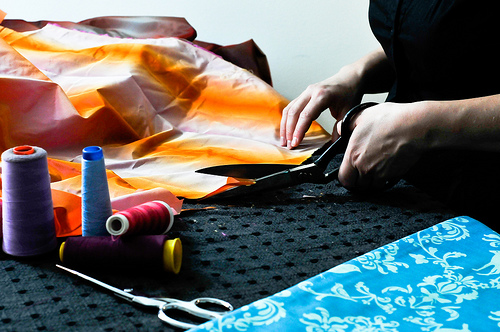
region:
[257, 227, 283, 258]
part of a cloth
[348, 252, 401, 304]
part of a cloth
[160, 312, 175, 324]
edge of a handle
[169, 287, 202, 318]
part of a scissor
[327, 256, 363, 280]
edge of a cloth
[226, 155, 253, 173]
edge of a scissor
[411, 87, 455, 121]
edge of an arm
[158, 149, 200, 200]
part of a cloth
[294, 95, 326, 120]
part of a finger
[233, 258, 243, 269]
black hole is spotted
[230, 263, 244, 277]
black hole is spotted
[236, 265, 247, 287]
black hole is spotted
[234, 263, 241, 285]
black hole is spotted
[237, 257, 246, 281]
black hole is spotted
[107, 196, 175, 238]
Spool of red thread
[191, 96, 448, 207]
Person holding scissors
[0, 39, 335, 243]
An orange and white fabric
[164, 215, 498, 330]
Blue fabric with white pattern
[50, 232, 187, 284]
spool of dark colored thread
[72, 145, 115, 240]
Blue spool with white thread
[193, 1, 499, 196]
woman cutting orange fabric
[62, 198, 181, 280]
spool of red thread on top of yellow spool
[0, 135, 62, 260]
white thread on orange spool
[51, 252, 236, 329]
scissors next to spool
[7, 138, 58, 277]
A spool of purple thread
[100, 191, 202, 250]
A spool of red thread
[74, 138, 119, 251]
A spool of blue thread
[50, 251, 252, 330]
A pair of scissors laying on the cloth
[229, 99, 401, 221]
A pair of scissors in a hand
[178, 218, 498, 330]
A blue cloth with white design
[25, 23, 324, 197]
A orange and white fabric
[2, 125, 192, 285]
Four spools of thread on cloth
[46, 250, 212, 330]
A pair of silver scissors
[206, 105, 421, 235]
A pair of scissors with black handle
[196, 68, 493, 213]
Woman cutting material with scissors.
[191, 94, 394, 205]
Large scissors in woman's hand.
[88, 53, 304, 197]
Orange and white material being cut by scissors.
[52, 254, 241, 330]
Silver scissors lying on work table.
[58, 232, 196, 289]
Purple spool of tread lying on work table.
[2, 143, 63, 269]
Lavender spool of thread sitting on work table.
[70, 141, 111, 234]
Blue spool of thread sitting on work table.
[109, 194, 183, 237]
Red spool of thread lying on work table.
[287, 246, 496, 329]
Light blue material with white flower designs.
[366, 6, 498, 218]
Woman dressed in black blouse.